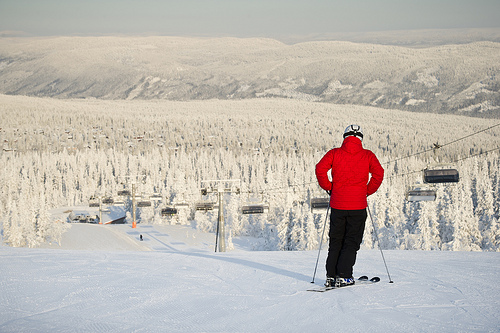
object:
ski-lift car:
[422, 169, 459, 184]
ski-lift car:
[311, 197, 330, 208]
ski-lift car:
[242, 204, 264, 214]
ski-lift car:
[161, 207, 177, 216]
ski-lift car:
[196, 203, 214, 210]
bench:
[421, 168, 460, 183]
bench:
[242, 205, 263, 213]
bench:
[310, 198, 329, 208]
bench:
[405, 188, 437, 202]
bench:
[161, 207, 177, 217]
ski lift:
[222, 179, 318, 193]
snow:
[25, 140, 101, 189]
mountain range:
[1, 36, 237, 103]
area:
[2, 0, 500, 330]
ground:
[431, 249, 461, 266]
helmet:
[343, 124, 364, 141]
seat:
[423, 169, 459, 183]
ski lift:
[133, 191, 228, 252]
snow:
[42, 70, 129, 134]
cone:
[132, 221, 137, 228]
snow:
[196, 125, 290, 153]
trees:
[101, 134, 197, 196]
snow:
[424, 286, 489, 332]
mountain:
[1, 16, 136, 90]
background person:
[140, 235, 144, 242]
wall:
[243, 113, 307, 136]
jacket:
[315, 136, 384, 210]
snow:
[3, 309, 38, 329]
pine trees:
[3, 95, 497, 250]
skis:
[306, 276, 380, 292]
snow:
[129, 305, 277, 328]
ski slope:
[20, 231, 472, 320]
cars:
[196, 203, 215, 211]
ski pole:
[366, 204, 393, 283]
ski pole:
[310, 201, 330, 283]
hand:
[324, 182, 334, 196]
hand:
[366, 184, 372, 197]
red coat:
[315, 134, 384, 210]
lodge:
[66, 210, 100, 224]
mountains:
[0, 26, 500, 118]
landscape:
[0, 28, 500, 248]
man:
[315, 124, 384, 287]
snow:
[101, 232, 223, 263]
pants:
[326, 206, 368, 277]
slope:
[108, 222, 288, 286]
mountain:
[409, 42, 498, 121]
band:
[343, 131, 363, 139]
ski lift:
[97, 183, 137, 228]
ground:
[4, 256, 201, 329]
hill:
[1, 224, 500, 333]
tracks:
[5, 272, 162, 331]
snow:
[397, 75, 480, 129]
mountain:
[180, 31, 362, 125]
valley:
[2, 151, 500, 246]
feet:
[323, 275, 354, 287]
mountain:
[5, 241, 475, 328]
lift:
[11, 120, 93, 253]